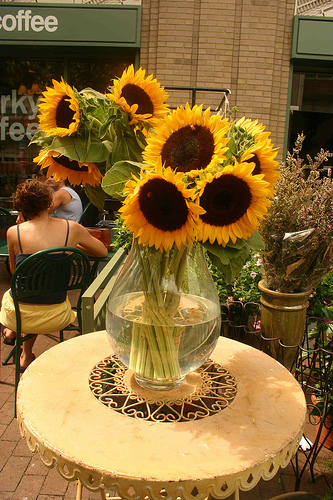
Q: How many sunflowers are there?
A: 6.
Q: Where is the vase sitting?
A: The table.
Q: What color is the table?
A: White.